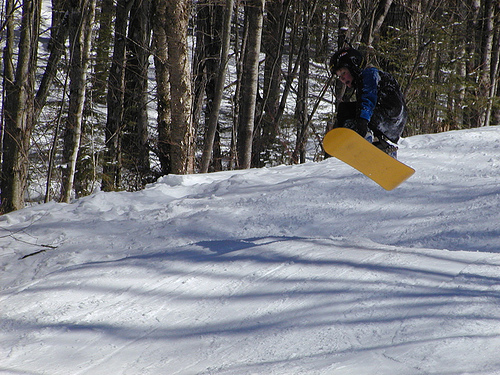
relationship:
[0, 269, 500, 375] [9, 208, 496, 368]
snow on ground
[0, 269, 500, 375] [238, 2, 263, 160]
snow near tree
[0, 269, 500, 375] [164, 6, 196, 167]
snow near tree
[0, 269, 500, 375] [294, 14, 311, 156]
snow near tree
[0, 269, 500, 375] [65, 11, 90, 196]
snow near tree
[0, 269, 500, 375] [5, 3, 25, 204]
snow near tree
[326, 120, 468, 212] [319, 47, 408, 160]
snowboard under boy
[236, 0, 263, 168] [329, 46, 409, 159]
tree behind kid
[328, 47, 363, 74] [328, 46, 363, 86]
helmet on head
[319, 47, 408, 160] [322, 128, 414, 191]
boy has snowboard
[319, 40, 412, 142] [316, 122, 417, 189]
boy on snowboard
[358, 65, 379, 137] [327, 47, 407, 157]
arm on snowboarder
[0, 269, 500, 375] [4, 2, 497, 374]
snow on hill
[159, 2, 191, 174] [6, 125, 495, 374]
tree on slope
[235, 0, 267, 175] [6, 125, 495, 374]
tree on slope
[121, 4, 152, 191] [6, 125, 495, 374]
tree on slope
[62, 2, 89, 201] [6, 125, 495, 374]
tree on slope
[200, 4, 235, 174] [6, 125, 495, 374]
tree on slope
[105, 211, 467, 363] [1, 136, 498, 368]
snow on ground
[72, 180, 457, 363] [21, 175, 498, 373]
shadows on snow